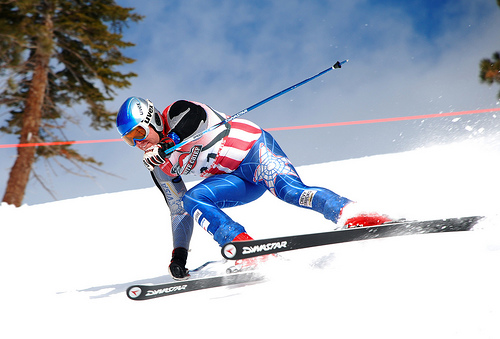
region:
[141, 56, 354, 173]
blue ski pole in a skier's hand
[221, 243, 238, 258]
white and red circular design on a ski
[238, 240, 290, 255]
white print on a black ski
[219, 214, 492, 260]
black ski attached to the man's foot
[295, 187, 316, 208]
white and black design on blue pants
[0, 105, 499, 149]
long red light behind a skier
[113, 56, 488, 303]
man on skis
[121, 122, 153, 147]
goggles over a skier's eyes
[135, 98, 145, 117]
black print on a helmet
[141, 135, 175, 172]
black white and red gloves on a skier's hand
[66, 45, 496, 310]
skier racing down hill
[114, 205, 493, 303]
black skis of skier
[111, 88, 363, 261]
blue, white, red, and black suit of skier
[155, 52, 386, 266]
blue ski poles of skier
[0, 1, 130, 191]
tree on side of mountain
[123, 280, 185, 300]
white lettering on black ski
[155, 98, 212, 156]
black strip on sleeve of ski suit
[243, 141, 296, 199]
star on leg of ski suit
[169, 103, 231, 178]
white race bib of skier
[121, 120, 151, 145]
white snow goggles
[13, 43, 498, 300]
A person with snowboarding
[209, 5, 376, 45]
A blue color sky with clouds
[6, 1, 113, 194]
Tree with branches in the snow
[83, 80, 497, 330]
A person playing in the snowboard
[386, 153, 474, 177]
White color snow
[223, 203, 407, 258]
Pair of shoes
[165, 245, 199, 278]
A person wearing black color glove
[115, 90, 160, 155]
A peraon wearing helmet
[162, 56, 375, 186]
A person holding the skipole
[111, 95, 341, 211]
A person wearing the snowboard suit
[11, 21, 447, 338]
picture taken outdoors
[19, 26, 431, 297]
picture taken outside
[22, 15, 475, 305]
a man skiing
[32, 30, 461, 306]
the man skis down hill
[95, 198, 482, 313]
the man has two skies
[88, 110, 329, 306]
the man holds ski poles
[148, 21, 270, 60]
the sky is partially cloudy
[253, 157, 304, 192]
the man wears blue ski pants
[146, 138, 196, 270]
the man wears ski gloves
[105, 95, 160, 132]
Blue and silver helmet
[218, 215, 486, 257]
A skiing board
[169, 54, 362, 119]
a skiing stroke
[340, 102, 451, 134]
A rope in the photo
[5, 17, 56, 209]
A tree trunk in the photo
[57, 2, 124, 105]
leaves in the background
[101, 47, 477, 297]
A person skiing on ice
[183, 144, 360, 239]
Blue pants in the photo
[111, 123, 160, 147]
Goggles in the photo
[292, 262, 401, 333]
Ice on the surface